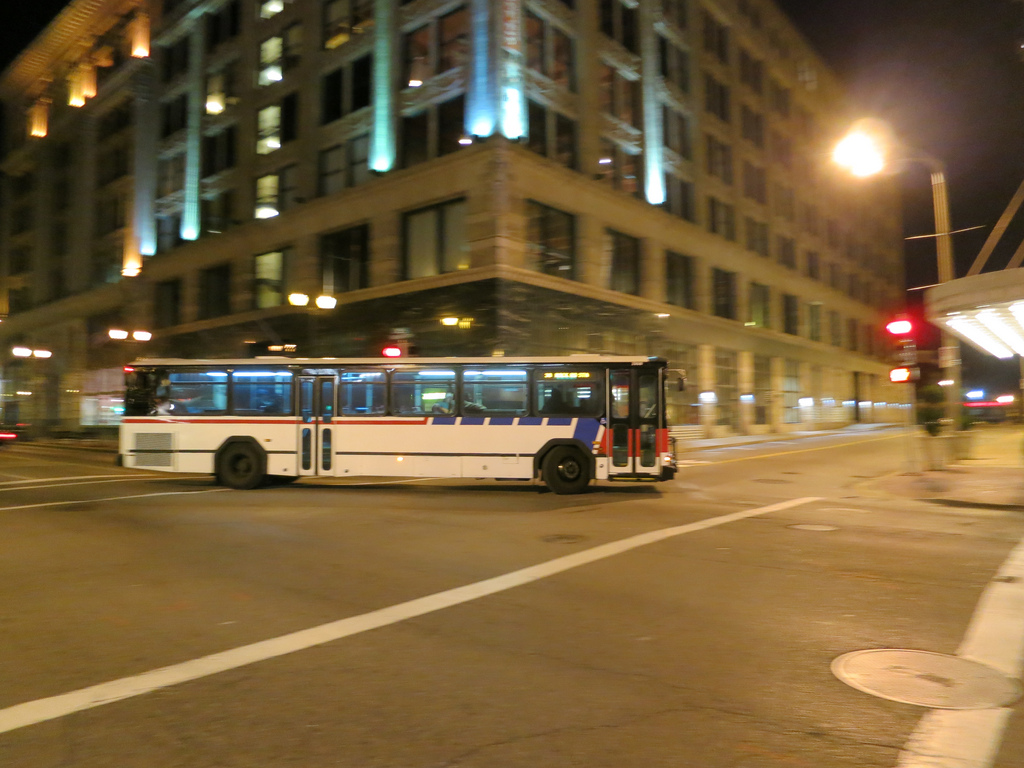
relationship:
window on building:
[747, 277, 773, 330] [0, 5, 925, 431]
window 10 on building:
[194, 185, 246, 240] [0, 5, 925, 431]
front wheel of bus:
[538, 443, 593, 492] [114, 349, 702, 490]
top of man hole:
[830, 629, 1018, 718] [826, 649, 1009, 714]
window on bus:
[389, 364, 454, 415] [114, 349, 702, 490]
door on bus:
[608, 364, 657, 473] [114, 349, 702, 490]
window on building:
[398, 209, 443, 283] [0, 5, 925, 431]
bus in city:
[114, 349, 702, 490] [17, 27, 1016, 760]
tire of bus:
[212, 440, 270, 489] [114, 349, 702, 490]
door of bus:
[288, 354, 342, 479] [114, 349, 702, 490]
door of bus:
[608, 364, 657, 473] [114, 349, 702, 490]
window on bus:
[231, 361, 292, 412] [117, 345, 690, 500]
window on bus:
[344, 354, 386, 412] [117, 345, 690, 500]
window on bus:
[389, 364, 453, 415] [117, 345, 690, 500]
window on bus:
[456, 357, 530, 418] [117, 345, 690, 500]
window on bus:
[528, 373, 596, 415] [117, 345, 690, 500]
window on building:
[200, 267, 233, 312] [0, 5, 925, 431]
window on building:
[338, 219, 380, 287] [0, 5, 925, 431]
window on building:
[247, 101, 282, 158] [0, 5, 925, 431]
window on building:
[521, 7, 548, 75] [0, 5, 925, 431]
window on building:
[515, 84, 558, 149] [0, 5, 925, 431]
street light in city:
[819, 115, 979, 467] [17, 27, 1016, 760]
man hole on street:
[825, 649, 1007, 714] [0, 405, 1022, 764]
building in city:
[0, 5, 925, 431] [17, 27, 1016, 760]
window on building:
[427, 0, 494, 90] [0, 5, 925, 431]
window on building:
[303, 53, 384, 112] [0, 5, 925, 431]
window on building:
[389, 9, 429, 90] [0, 5, 925, 431]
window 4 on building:
[251, 26, 297, 97] [25, 115, 1008, 615]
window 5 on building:
[519, 188, 589, 284] [21, 121, 951, 435]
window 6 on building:
[592, 48, 656, 140] [17, 128, 916, 602]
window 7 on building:
[594, 125, 655, 203] [21, 121, 951, 435]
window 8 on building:
[658, 96, 698, 167] [12, 113, 909, 550]